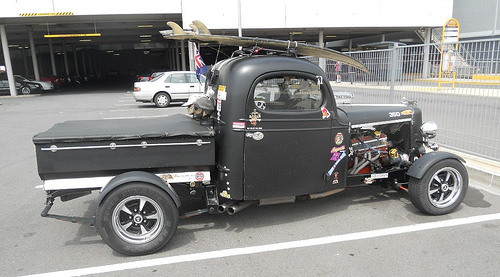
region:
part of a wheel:
[457, 215, 472, 227]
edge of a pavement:
[301, 225, 312, 242]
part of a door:
[258, 121, 270, 163]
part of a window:
[248, 103, 260, 116]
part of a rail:
[419, 102, 427, 114]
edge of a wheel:
[436, 162, 441, 181]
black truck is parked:
[42, 88, 447, 238]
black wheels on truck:
[86, 174, 199, 249]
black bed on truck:
[27, 94, 221, 204]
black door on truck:
[222, 47, 372, 214]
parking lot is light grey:
[169, 204, 393, 259]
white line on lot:
[207, 199, 374, 274]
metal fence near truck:
[392, 27, 493, 119]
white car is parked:
[110, 56, 213, 104]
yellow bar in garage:
[30, 24, 111, 44]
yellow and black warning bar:
[25, 5, 77, 26]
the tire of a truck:
[93, 170, 182, 257]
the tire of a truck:
[403, 150, 470, 216]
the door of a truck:
[241, 66, 333, 196]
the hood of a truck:
[337, 95, 415, 118]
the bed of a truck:
[33, 112, 213, 142]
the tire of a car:
[152, 89, 171, 108]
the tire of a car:
[18, 85, 33, 95]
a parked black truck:
[30, 50, 470, 256]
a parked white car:
[128, 70, 235, 105]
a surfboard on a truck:
[154, 20, 376, 72]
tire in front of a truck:
[407, 142, 465, 220]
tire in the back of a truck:
[80, 178, 178, 255]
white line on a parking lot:
[186, 234, 228, 270]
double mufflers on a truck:
[217, 196, 242, 220]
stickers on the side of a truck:
[316, 96, 348, 202]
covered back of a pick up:
[17, 109, 217, 177]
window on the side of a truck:
[244, 64, 328, 121]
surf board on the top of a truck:
[154, 11, 381, 86]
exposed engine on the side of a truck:
[339, 113, 409, 185]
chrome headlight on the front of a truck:
[422, 113, 441, 152]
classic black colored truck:
[28, 51, 473, 258]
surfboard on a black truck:
[153, 15, 377, 76]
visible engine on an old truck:
[346, 124, 414, 176]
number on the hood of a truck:
[386, 111, 401, 120]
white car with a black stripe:
[132, 67, 218, 107]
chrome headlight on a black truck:
[416, 117, 441, 151]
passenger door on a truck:
[242, 65, 349, 200]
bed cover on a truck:
[35, 113, 216, 143]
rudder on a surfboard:
[158, 15, 214, 35]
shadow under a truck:
[66, 169, 492, 249]